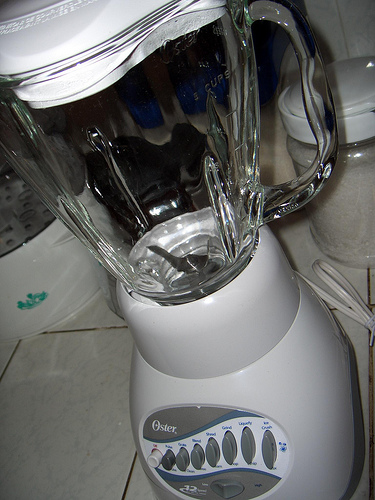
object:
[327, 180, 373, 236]
storage jar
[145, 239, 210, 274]
oster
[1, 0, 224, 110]
cover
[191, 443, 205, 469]
button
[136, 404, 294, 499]
controller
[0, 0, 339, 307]
glass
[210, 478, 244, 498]
button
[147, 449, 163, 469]
button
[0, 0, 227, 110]
lid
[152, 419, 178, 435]
brand name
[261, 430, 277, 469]
grey button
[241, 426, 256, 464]
grey button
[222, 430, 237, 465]
grey button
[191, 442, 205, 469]
grey button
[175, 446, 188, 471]
grey button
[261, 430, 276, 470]
button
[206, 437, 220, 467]
button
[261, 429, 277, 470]
chair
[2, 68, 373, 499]
tile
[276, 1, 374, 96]
tile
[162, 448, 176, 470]
button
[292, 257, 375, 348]
cord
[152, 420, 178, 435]
oster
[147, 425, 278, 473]
buttons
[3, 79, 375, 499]
surface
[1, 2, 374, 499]
blender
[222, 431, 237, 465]
button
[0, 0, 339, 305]
jar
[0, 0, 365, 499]
white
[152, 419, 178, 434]
symbol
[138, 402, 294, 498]
button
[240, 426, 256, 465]
button